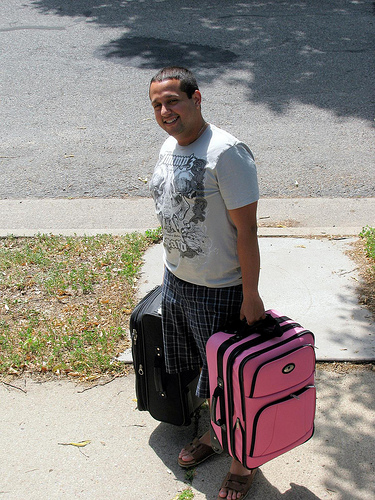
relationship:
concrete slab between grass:
[276, 241, 332, 341] [31, 239, 86, 362]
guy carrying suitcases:
[150, 66, 265, 499] [217, 308, 322, 487]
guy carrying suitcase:
[150, 66, 265, 499] [199, 304, 317, 469]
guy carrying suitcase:
[150, 66, 265, 499] [126, 281, 187, 424]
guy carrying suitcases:
[150, 66, 265, 499] [128, 281, 318, 471]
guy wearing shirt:
[150, 66, 265, 499] [149, 124, 259, 288]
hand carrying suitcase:
[240, 296, 265, 324] [199, 304, 317, 469]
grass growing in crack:
[176, 465, 194, 498] [179, 407, 200, 497]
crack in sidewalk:
[179, 407, 200, 497] [2, 237, 371, 497]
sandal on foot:
[175, 437, 219, 468] [178, 424, 215, 461]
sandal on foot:
[215, 467, 256, 498] [217, 458, 251, 499]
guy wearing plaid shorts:
[140, 49, 285, 498] [161, 265, 242, 399]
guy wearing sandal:
[150, 66, 265, 499] [177, 436, 215, 469]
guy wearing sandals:
[150, 66, 265, 499] [219, 468, 257, 499]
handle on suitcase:
[218, 316, 284, 337] [212, 324, 322, 461]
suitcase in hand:
[199, 304, 317, 469] [239, 296, 266, 325]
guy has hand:
[150, 66, 265, 499] [239, 296, 266, 325]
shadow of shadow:
[128, 17, 367, 154] [20, 0, 373, 128]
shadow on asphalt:
[128, 17, 367, 154] [2, 2, 373, 227]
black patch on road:
[92, 29, 238, 83] [1, 1, 373, 228]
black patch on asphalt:
[88, 28, 242, 87] [0, 0, 375, 229]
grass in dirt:
[45, 299, 112, 373] [23, 287, 49, 310]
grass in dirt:
[45, 299, 112, 373] [91, 284, 101, 297]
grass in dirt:
[50, 325, 112, 374] [56, 299, 70, 311]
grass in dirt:
[45, 299, 112, 373] [30, 373, 56, 380]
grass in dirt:
[45, 299, 112, 373] [99, 242, 117, 252]